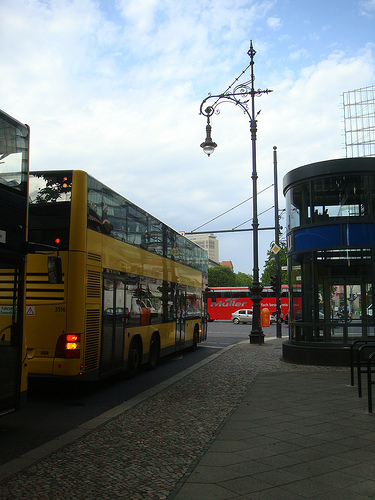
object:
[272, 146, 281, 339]
post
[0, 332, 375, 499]
sidewalk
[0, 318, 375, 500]
road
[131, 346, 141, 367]
rim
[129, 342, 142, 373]
tire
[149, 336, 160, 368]
tire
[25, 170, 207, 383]
bus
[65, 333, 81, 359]
tail light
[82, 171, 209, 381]
side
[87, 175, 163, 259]
window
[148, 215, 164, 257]
window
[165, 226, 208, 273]
window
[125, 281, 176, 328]
window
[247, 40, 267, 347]
post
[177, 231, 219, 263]
building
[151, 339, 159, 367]
rim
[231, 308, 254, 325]
car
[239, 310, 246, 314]
window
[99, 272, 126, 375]
door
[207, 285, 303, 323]
bus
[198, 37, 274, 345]
light post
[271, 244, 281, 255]
diamond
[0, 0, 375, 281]
sky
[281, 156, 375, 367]
building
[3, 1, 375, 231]
clouds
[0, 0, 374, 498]
city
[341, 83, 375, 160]
scaffolding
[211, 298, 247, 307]
logo